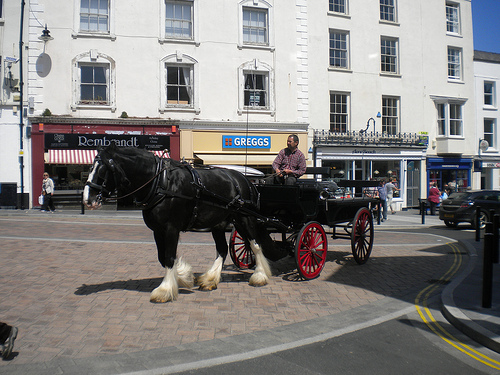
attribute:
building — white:
[66, 7, 417, 159]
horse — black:
[68, 145, 265, 243]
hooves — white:
[142, 261, 290, 314]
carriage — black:
[255, 178, 382, 237]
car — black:
[437, 186, 494, 239]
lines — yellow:
[414, 301, 458, 350]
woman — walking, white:
[36, 167, 61, 213]